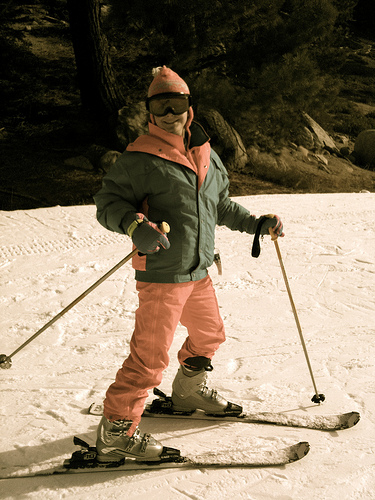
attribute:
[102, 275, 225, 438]
snow pants — pink, orange, peach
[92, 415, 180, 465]
ski boot — silver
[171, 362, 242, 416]
ski boot — silver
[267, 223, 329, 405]
ski pole — silver, long, metal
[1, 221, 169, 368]
ski pole — silver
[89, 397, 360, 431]
ski — black, long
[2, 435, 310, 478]
ski — black, long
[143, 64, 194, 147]
hat — pink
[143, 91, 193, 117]
goggles — black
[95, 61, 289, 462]
skier — smiling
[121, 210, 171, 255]
glove — olive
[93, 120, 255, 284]
jacket — olive green, green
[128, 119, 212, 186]
trim — peach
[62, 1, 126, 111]
tree — rough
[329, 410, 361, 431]
tip — turned up